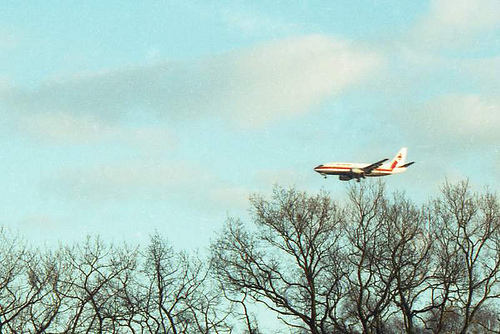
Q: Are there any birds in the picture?
A: No, there are no birds.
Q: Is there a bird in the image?
A: No, there are no birds.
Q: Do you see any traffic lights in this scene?
A: No, there are no traffic lights.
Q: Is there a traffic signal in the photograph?
A: No, there are no traffic lights.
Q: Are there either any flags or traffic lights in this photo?
A: No, there are no traffic lights or flags.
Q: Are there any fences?
A: No, there are no fences.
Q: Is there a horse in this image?
A: No, there are no horses.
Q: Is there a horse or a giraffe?
A: No, there are no horses or giraffes.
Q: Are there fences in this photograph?
A: No, there are no fences.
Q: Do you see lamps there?
A: No, there are no lamps.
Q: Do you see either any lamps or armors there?
A: No, there are no lamps or armors.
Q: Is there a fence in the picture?
A: No, there are no fences.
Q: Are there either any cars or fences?
A: No, there are no fences or cars.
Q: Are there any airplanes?
A: Yes, there is an airplane.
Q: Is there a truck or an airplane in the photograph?
A: Yes, there is an airplane.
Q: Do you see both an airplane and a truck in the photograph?
A: No, there is an airplane but no trucks.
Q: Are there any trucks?
A: No, there are no trucks.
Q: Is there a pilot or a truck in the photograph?
A: No, there are no trucks or pilots.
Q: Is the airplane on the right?
A: Yes, the airplane is on the right of the image.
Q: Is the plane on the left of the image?
A: No, the plane is on the right of the image.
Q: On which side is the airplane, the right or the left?
A: The airplane is on the right of the image.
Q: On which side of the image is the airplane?
A: The airplane is on the right of the image.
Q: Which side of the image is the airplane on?
A: The airplane is on the right of the image.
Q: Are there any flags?
A: No, there are no flags.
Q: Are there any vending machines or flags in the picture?
A: No, there are no flags or vending machines.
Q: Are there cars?
A: No, there are no cars.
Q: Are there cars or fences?
A: No, there are no cars or fences.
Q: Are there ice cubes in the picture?
A: No, there are no ice cubes.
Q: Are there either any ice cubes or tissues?
A: No, there are no ice cubes or tissues.